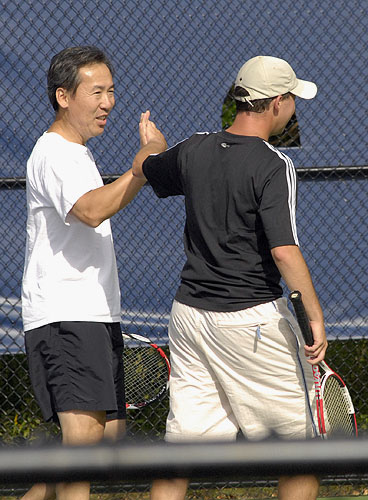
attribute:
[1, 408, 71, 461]
grass — green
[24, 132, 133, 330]
shirt — white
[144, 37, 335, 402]
player — tennis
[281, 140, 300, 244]
stripes — white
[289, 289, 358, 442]
racket — white, red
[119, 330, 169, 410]
racket — red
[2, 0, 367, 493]
fence — metal, chain link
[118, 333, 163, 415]
racket — red, white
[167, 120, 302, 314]
shirt — black, white strips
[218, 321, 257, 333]
pocket — zippered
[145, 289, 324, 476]
shorts — white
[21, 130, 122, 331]
shirt — white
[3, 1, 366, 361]
wall — blue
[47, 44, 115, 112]
hair — black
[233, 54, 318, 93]
hat — white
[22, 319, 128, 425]
shorts — black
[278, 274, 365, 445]
racket — black, red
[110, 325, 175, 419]
racket — black, red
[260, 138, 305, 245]
stripes — white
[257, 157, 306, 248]
sleeve — white, stripes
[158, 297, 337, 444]
shorts — white, blue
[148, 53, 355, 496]
players — tennis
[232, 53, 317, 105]
cap — tan, baseball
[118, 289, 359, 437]
rackets — tennis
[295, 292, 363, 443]
racket — red, black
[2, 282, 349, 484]
court — tennis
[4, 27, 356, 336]
screen — blue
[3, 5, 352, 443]
fence — chain-link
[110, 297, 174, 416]
racket — tennis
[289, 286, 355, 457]
racket — tennis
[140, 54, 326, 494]
player — tennis